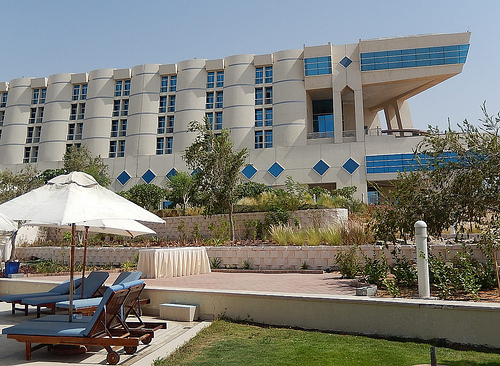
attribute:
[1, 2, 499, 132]
sky — close, clear, blue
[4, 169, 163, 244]
umbrella — in, short, white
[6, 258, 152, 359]
chairs — blue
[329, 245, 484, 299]
shrubs — small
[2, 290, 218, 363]
pool deck — tiled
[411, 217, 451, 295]
barricade — white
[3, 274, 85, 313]
chair — blue, reclining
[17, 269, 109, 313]
chair — blue, reclining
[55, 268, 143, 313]
chair — blue, reclining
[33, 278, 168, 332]
chair — blue, reclining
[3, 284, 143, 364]
chair — blue, reclining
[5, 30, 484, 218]
building — large, wide, big, blue, white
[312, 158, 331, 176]
design — blue, diamond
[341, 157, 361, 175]
design — blue, diamond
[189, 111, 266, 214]
leaves — green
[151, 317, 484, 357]
ground surface — green, grass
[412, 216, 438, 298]
pole — white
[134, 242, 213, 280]
table — buffet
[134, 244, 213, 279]
curtain — white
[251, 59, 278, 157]
windows — blue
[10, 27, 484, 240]
building — white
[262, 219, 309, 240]
grass — above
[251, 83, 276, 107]
window — in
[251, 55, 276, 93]
window — in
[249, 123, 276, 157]
window — in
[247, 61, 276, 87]
window — in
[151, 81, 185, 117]
window — in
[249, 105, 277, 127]
window — in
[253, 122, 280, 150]
window — in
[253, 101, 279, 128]
window — in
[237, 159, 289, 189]
diamonds — on